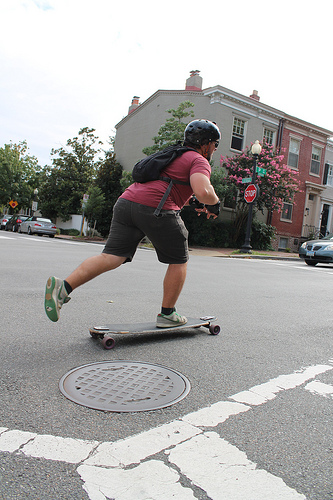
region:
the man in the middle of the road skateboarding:
[41, 114, 225, 344]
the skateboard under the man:
[80, 313, 223, 342]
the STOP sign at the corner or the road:
[243, 184, 253, 202]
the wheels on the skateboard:
[84, 325, 221, 346]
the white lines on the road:
[10, 363, 330, 497]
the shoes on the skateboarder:
[38, 272, 182, 328]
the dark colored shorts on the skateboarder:
[99, 190, 186, 259]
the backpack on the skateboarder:
[129, 137, 189, 184]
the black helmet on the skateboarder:
[184, 118, 217, 140]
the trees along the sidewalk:
[1, 97, 295, 245]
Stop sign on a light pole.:
[242, 178, 259, 212]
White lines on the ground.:
[30, 361, 330, 498]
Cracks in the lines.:
[8, 421, 184, 474]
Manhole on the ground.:
[49, 345, 197, 422]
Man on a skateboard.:
[35, 110, 249, 360]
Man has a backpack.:
[130, 134, 203, 188]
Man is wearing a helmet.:
[176, 112, 229, 154]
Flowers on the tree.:
[227, 145, 298, 213]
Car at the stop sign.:
[292, 225, 331, 261]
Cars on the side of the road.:
[4, 211, 61, 235]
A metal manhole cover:
[41, 351, 204, 429]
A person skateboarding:
[38, 117, 224, 361]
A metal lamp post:
[237, 136, 270, 255]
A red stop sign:
[240, 181, 266, 205]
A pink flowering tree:
[221, 133, 303, 232]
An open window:
[228, 108, 255, 158]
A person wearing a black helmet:
[165, 101, 233, 157]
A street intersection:
[3, 237, 330, 490]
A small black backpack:
[130, 124, 208, 199]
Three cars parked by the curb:
[0, 211, 59, 238]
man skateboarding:
[37, 110, 226, 323]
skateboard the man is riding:
[81, 313, 235, 352]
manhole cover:
[52, 351, 193, 415]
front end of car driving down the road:
[297, 233, 328, 261]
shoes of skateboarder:
[37, 272, 194, 332]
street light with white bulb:
[242, 133, 261, 256]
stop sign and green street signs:
[234, 158, 272, 210]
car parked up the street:
[10, 208, 64, 243]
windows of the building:
[216, 113, 329, 245]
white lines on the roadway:
[0, 359, 331, 498]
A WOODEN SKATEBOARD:
[88, 313, 223, 352]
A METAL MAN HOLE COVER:
[53, 356, 198, 415]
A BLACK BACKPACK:
[127, 140, 196, 194]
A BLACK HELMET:
[178, 112, 225, 150]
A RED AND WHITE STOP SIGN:
[239, 180, 260, 205]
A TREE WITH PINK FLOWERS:
[219, 136, 306, 227]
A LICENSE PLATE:
[300, 248, 320, 259]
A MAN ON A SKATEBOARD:
[44, 115, 237, 350]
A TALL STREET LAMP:
[238, 135, 267, 257]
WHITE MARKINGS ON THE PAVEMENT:
[38, 412, 294, 497]